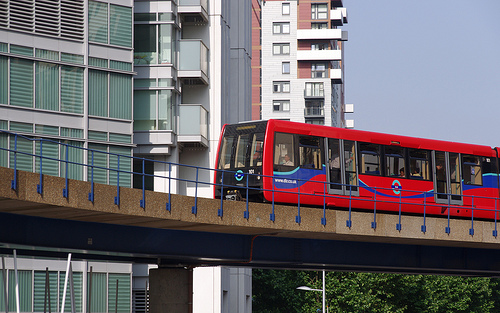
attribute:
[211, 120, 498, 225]
train — elevated, red, black, driving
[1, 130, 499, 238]
railing — blue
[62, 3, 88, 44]
blinds — horizontal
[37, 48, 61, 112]
curtains — vertical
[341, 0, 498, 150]
sky — blue, clear, gray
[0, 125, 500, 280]
bridge — blue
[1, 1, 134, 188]
building — tall, high